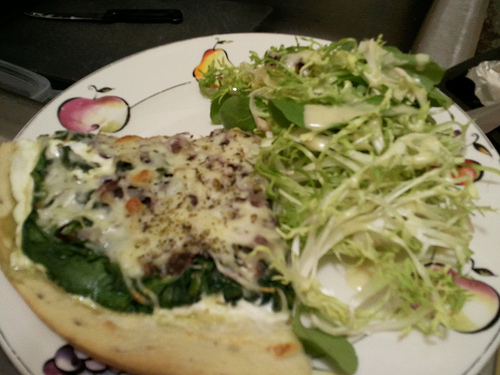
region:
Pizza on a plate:
[0, 120, 315, 373]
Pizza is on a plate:
[2, 120, 315, 370]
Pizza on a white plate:
[0, 126, 312, 372]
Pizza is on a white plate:
[0, 116, 320, 371]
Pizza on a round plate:
[1, 115, 306, 372]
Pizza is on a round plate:
[0, 120, 310, 372]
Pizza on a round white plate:
[2, 122, 312, 373]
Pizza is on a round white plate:
[1, 122, 317, 373]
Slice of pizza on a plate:
[0, 122, 317, 373]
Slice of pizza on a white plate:
[0, 114, 319, 370]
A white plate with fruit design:
[22, 66, 497, 356]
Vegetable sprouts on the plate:
[280, 136, 466, 336]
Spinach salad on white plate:
[211, 55, 411, 125]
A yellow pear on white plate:
[180, 40, 230, 85]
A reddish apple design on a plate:
[55, 85, 145, 136]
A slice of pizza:
[5, 131, 305, 367]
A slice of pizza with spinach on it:
[16, 125, 272, 335]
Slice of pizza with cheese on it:
[30, 140, 251, 290]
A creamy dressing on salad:
[246, 30, 382, 127]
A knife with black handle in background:
[18, 0, 201, 30]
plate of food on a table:
[9, 8, 496, 371]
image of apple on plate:
[60, 78, 152, 140]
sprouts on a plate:
[329, 160, 441, 302]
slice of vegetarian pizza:
[12, 103, 290, 374]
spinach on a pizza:
[37, 230, 111, 310]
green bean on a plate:
[296, 323, 370, 368]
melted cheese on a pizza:
[127, 141, 247, 231]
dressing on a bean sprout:
[307, 103, 349, 131]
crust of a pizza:
[111, 323, 280, 364]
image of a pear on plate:
[189, 34, 241, 89]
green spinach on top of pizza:
[46, 232, 174, 314]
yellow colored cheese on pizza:
[114, 227, 140, 256]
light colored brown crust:
[143, 329, 245, 366]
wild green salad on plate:
[312, 184, 409, 271]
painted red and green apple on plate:
[63, 86, 160, 137]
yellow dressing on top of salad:
[302, 106, 357, 170]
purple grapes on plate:
[31, 337, 87, 372]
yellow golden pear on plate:
[198, 39, 238, 97]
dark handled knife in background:
[29, 7, 187, 44]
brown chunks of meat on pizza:
[166, 135, 198, 156]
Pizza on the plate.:
[0, 130, 310, 373]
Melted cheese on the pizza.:
[57, 140, 261, 252]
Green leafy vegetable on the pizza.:
[26, 145, 291, 321]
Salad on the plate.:
[202, 43, 471, 331]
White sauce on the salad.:
[296, 96, 366, 148]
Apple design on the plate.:
[56, 83, 136, 134]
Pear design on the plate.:
[190, 34, 232, 89]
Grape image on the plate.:
[37, 337, 116, 374]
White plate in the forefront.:
[3, 25, 498, 371]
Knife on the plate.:
[27, 6, 193, 28]